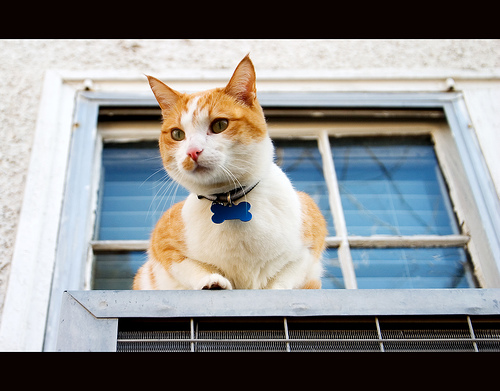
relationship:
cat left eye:
[133, 52, 330, 292] [208, 118, 229, 133]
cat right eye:
[133, 52, 330, 292] [171, 127, 185, 140]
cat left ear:
[133, 52, 330, 292] [228, 54, 257, 104]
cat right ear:
[133, 52, 330, 292] [145, 74, 181, 108]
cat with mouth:
[133, 52, 330, 292] [186, 158, 215, 176]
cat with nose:
[133, 52, 330, 292] [186, 148, 204, 161]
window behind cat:
[90, 134, 476, 288] [133, 52, 330, 292]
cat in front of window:
[133, 52, 330, 292] [90, 134, 476, 288]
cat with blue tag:
[133, 52, 330, 292] [209, 201, 252, 223]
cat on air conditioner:
[133, 52, 330, 292] [54, 290, 500, 353]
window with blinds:
[90, 134, 476, 288] [93, 148, 470, 289]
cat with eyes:
[133, 52, 330, 292] [172, 118, 228, 141]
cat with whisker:
[133, 52, 330, 292] [143, 163, 272, 214]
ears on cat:
[146, 53, 258, 109] [133, 52, 330, 292]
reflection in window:
[278, 142, 450, 233] [90, 134, 476, 288]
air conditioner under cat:
[54, 290, 500, 353] [133, 52, 330, 292]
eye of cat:
[208, 118, 229, 133] [133, 52, 330, 292]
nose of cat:
[186, 148, 204, 161] [133, 52, 330, 292]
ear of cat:
[228, 54, 257, 104] [133, 52, 330, 292]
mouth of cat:
[186, 158, 215, 176] [133, 52, 330, 292]